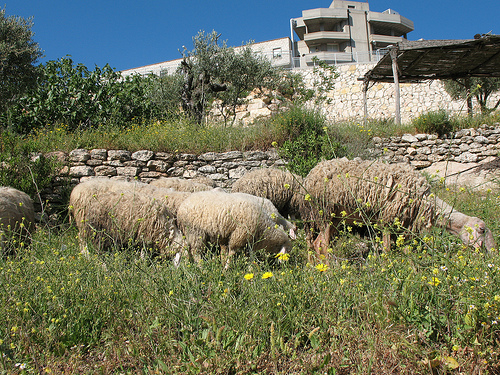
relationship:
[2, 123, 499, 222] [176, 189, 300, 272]
wall behind sheep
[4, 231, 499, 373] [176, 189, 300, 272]
grass in front of sheep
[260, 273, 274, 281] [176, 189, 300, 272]
flowers in front of sheep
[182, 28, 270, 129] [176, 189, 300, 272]
trees behind sheep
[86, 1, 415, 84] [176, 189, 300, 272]
building above sheep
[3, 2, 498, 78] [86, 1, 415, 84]
sky behind building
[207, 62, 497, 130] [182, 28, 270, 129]
wall behind trees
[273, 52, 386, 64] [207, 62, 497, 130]
fence over wall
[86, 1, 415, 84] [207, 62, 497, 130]
building behind wall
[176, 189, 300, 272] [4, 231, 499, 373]
sheep eating grass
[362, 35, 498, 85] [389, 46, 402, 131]
roof on supports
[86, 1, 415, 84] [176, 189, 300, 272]
building behind sheep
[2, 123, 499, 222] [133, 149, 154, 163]
wall made of rocks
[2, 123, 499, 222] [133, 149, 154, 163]
wall made of stones